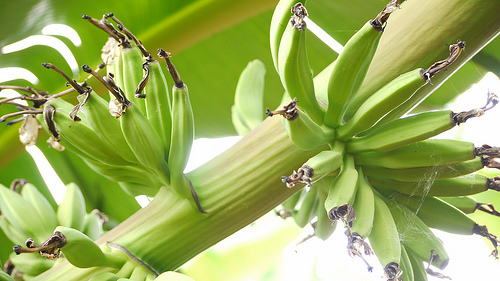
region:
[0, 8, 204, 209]
flowerless greenery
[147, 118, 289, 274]
stalk of plant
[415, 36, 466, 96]
dried-up remnants after blooming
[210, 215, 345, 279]
blinding natural light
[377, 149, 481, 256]
spider webs on plant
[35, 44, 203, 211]
flowerless green tips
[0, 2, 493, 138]
giant green leaf in background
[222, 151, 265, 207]
parallel grooves on plant's body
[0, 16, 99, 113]
bright fluorescent beams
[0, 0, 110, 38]
slight visual distortion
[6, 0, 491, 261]
The stem of a plant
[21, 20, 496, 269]
This stem is long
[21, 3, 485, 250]
The stem is pale green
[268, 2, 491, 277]
This is a blossom on the stalk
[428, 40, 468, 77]
The blossom is brown at the top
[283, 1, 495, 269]
The blossom is no longer flowering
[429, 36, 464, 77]
The top of the blossom is dried up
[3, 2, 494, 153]
A green leaf is behind the stalk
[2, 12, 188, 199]
There is another blossom on the plant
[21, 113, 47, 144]
Faded white petals on the plant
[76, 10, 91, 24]
tiny purple blade on stalk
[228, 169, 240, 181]
groove on green stalk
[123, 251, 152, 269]
line on green stalk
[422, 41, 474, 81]
large bud on end of stalk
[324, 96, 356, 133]
narrow green base on green stalk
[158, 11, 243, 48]
large lime green branch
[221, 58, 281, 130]
single green leaf from stalk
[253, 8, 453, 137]
bunch of green bunches on stalk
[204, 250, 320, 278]
large creamy white surface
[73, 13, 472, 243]
huge green stalk with green bunches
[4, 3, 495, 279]
sunlight shining through green plant material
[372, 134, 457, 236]
a tiny spider web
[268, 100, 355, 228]
tiny immature bananas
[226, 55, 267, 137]
the backside of green plant parts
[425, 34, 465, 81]
the dead remnant of a blossom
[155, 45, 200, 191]
one green seed pod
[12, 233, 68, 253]
a dying stamen from a blossom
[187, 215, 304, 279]
a mature yellow banana in the background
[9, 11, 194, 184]
a cluster of tiny baby bananas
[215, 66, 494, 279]
a bright light is in the background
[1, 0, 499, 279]
banana plant is chartreuse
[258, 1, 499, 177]
largest part of banana plant limb is also pastel yellow green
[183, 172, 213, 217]
banana bunch starts here when growing from banana plant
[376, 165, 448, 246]
wispy spiderweb among banana bunch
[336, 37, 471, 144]
banana is thin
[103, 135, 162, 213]
banana stem is curled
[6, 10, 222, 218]
bananas are an exotic variety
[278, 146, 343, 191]
banana is unripe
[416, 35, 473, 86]
end of banana: last of perianth+stigma+style is very long [that really is what it's called]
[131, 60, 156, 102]
remnants of banana flower has peculiar twisty shape